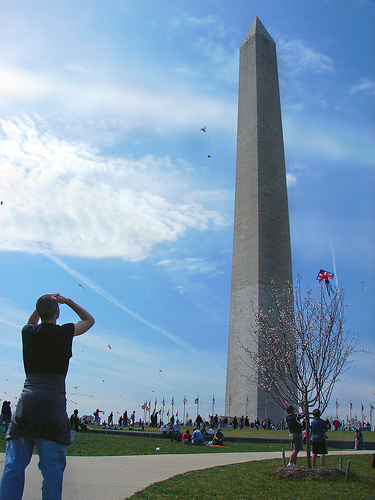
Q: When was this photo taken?
A: In the daytime.